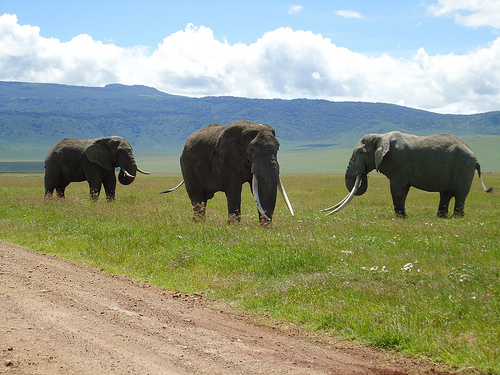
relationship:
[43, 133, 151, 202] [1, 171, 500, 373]
elephant walking on ground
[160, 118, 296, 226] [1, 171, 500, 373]
elephant walking on ground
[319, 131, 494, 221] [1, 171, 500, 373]
elephant walking on ground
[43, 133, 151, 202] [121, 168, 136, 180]
elephant with tusk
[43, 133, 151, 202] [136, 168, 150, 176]
elephant with tusk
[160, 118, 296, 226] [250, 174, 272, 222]
elephant with tusk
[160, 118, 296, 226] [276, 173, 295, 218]
elephant with tusk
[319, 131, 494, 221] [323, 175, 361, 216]
elephant with tusk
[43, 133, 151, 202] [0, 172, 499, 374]
elephant walking on grass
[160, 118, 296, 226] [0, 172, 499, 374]
elephant walking on grass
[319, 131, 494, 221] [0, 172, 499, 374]
elephant walking on grass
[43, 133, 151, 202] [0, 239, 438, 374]
elephant walking near road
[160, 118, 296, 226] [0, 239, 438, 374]
elephant walking near road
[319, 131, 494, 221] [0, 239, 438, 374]
elephant walking near road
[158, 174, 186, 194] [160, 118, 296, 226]
tail of elephant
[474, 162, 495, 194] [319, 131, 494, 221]
tail of elephant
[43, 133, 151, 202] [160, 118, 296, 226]
elephant behind elephant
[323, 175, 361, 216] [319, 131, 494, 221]
tusk on elephant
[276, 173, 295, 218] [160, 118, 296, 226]
tusk on elephant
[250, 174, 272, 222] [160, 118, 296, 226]
tusk on elephant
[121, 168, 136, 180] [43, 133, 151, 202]
tusk on elephant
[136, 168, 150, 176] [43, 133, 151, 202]
tusk on elephant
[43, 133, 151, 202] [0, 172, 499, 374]
elephant standing in grass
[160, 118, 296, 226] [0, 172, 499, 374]
elephant standing in grass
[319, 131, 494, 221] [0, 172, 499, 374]
elephant standing in grass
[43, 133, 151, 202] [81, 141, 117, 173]
elephant has ear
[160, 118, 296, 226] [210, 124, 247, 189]
elephant has ear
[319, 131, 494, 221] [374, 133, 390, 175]
elephant has ear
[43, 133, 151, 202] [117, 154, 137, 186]
elephant has trunk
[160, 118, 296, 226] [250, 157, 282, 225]
elephant has trunk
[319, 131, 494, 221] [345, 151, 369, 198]
elephant has trunk